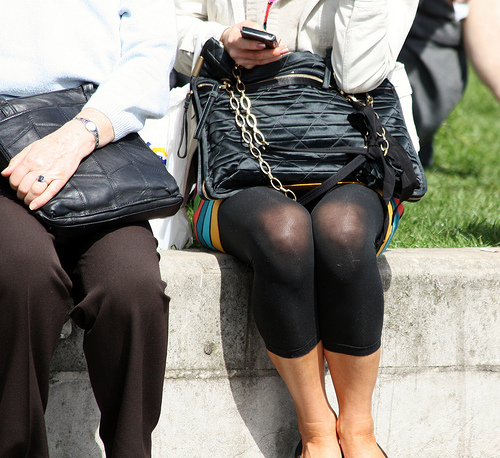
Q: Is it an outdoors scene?
A: Yes, it is outdoors.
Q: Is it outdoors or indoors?
A: It is outdoors.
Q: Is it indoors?
A: No, it is outdoors.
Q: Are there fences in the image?
A: No, there are no fences.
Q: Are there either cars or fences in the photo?
A: No, there are no fences or cars.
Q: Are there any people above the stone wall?
A: Yes, there are people above the wall.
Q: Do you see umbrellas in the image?
A: No, there are no umbrellas.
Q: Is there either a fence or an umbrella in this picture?
A: No, there are no umbrellas or fences.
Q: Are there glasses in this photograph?
A: No, there are no glasses.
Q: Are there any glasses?
A: No, there are no glasses.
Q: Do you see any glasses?
A: No, there are no glasses.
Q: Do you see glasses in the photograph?
A: No, there are no glasses.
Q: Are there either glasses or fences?
A: No, there are no glasses or fences.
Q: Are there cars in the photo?
A: No, there are no cars.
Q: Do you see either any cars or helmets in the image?
A: No, there are no cars or helmets.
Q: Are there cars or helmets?
A: No, there are no cars or helmets.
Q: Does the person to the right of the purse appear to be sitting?
A: Yes, the person is sitting.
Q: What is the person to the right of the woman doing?
A: The person is sitting.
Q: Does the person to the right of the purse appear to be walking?
A: No, the person is sitting.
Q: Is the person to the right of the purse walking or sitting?
A: The person is sitting.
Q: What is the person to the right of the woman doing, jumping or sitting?
A: The person is sitting.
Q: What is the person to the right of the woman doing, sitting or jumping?
A: The person is sitting.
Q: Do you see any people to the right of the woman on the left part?
A: Yes, there is a person to the right of the woman.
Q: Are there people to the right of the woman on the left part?
A: Yes, there is a person to the right of the woman.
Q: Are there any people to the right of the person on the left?
A: Yes, there is a person to the right of the woman.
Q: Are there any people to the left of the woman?
A: No, the person is to the right of the woman.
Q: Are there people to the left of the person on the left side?
A: No, the person is to the right of the woman.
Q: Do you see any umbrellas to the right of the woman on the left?
A: No, there is a person to the right of the woman.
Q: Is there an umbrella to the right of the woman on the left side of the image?
A: No, there is a person to the right of the woman.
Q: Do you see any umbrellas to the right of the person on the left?
A: No, there is a person to the right of the woman.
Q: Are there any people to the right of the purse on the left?
A: Yes, there is a person to the right of the purse.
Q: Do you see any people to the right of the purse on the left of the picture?
A: Yes, there is a person to the right of the purse.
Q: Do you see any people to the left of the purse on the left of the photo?
A: No, the person is to the right of the purse.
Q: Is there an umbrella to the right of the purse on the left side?
A: No, there is a person to the right of the purse.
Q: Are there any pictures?
A: No, there are no pictures.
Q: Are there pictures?
A: No, there are no pictures.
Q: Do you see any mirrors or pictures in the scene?
A: No, there are no pictures or mirrors.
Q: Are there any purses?
A: Yes, there is a purse.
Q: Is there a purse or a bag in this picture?
A: Yes, there is a purse.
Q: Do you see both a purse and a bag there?
A: Yes, there are both a purse and a bag.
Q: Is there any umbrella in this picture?
A: No, there are no umbrellas.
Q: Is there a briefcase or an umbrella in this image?
A: No, there are no umbrellas or briefcases.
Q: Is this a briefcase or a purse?
A: This is a purse.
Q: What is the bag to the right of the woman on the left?
A: The bag is a purse.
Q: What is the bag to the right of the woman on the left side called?
A: The bag is a purse.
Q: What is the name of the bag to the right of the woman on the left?
A: The bag is a purse.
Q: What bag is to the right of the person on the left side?
A: The bag is a purse.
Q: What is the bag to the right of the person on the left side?
A: The bag is a purse.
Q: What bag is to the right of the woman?
A: The bag is a purse.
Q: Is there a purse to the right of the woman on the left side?
A: Yes, there is a purse to the right of the woman.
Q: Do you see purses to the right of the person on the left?
A: Yes, there is a purse to the right of the woman.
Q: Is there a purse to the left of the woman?
A: No, the purse is to the right of the woman.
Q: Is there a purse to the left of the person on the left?
A: No, the purse is to the right of the woman.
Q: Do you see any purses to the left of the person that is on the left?
A: No, the purse is to the right of the woman.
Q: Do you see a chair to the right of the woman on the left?
A: No, there is a purse to the right of the woman.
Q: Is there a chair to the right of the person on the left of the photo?
A: No, there is a purse to the right of the woman.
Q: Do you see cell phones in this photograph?
A: Yes, there is a cell phone.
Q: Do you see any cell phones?
A: Yes, there is a cell phone.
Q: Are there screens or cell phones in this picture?
A: Yes, there is a cell phone.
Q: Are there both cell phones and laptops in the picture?
A: No, there is a cell phone but no laptops.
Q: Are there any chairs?
A: No, there are no chairs.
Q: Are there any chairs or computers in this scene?
A: No, there are no chairs or computers.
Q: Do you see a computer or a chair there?
A: No, there are no chairs or computers.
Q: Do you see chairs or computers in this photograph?
A: No, there are no chairs or computers.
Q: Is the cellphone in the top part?
A: Yes, the cellphone is in the top of the image.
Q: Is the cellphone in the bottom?
A: No, the cellphone is in the top of the image.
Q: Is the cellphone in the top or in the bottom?
A: The cellphone is in the top of the image.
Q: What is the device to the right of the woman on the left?
A: The device is a cell phone.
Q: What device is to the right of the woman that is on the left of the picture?
A: The device is a cell phone.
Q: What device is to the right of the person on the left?
A: The device is a cell phone.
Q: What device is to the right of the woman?
A: The device is a cell phone.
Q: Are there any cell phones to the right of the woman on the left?
A: Yes, there is a cell phone to the right of the woman.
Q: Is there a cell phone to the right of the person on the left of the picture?
A: Yes, there is a cell phone to the right of the woman.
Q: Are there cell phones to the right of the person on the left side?
A: Yes, there is a cell phone to the right of the woman.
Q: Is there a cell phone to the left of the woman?
A: No, the cell phone is to the right of the woman.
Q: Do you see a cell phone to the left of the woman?
A: No, the cell phone is to the right of the woman.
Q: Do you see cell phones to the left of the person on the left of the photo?
A: No, the cell phone is to the right of the woman.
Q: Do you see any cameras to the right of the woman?
A: No, there is a cell phone to the right of the woman.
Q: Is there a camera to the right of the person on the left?
A: No, there is a cell phone to the right of the woman.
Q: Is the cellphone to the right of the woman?
A: Yes, the cellphone is to the right of the woman.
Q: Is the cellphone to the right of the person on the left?
A: Yes, the cellphone is to the right of the woman.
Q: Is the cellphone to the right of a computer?
A: No, the cellphone is to the right of the woman.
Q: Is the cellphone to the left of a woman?
A: No, the cellphone is to the right of a woman.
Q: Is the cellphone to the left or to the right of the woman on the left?
A: The cellphone is to the right of the woman.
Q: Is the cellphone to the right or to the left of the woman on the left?
A: The cellphone is to the right of the woman.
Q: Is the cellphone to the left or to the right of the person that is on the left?
A: The cellphone is to the right of the woman.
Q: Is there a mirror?
A: No, there are no mirrors.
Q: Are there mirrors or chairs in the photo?
A: No, there are no mirrors or chairs.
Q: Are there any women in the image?
A: Yes, there is a woman.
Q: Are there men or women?
A: Yes, there is a woman.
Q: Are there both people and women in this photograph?
A: Yes, there are both a woman and a person.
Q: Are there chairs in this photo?
A: No, there are no chairs.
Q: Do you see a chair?
A: No, there are no chairs.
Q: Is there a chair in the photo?
A: No, there are no chairs.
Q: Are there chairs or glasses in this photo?
A: No, there are no chairs or glasses.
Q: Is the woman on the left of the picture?
A: Yes, the woman is on the left of the image.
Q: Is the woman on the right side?
A: No, the woman is on the left of the image.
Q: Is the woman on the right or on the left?
A: The woman is on the left of the image.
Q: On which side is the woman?
A: The woman is on the left of the image.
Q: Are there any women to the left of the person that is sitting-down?
A: Yes, there is a woman to the left of the person.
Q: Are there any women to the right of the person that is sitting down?
A: No, the woman is to the left of the person.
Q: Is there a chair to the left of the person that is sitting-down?
A: No, there is a woman to the left of the person.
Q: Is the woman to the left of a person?
A: Yes, the woman is to the left of a person.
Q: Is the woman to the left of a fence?
A: No, the woman is to the left of a person.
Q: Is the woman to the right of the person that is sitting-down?
A: No, the woman is to the left of the person.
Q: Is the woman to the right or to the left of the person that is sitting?
A: The woman is to the left of the person.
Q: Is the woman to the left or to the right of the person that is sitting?
A: The woman is to the left of the person.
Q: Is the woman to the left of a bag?
A: Yes, the woman is to the left of a bag.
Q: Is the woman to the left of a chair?
A: No, the woman is to the left of a bag.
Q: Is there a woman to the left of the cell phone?
A: Yes, there is a woman to the left of the cell phone.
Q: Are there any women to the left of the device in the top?
A: Yes, there is a woman to the left of the cell phone.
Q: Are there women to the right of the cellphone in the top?
A: No, the woman is to the left of the cell phone.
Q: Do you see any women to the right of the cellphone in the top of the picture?
A: No, the woman is to the left of the cell phone.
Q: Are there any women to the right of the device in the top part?
A: No, the woman is to the left of the cell phone.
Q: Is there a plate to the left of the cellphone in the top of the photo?
A: No, there is a woman to the left of the cell phone.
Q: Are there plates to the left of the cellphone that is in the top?
A: No, there is a woman to the left of the cell phone.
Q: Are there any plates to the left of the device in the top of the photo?
A: No, there is a woman to the left of the cell phone.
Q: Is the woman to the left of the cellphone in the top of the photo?
A: Yes, the woman is to the left of the cell phone.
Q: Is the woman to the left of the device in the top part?
A: Yes, the woman is to the left of the cell phone.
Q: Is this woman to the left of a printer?
A: No, the woman is to the left of the cell phone.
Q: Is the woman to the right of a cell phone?
A: No, the woman is to the left of a cell phone.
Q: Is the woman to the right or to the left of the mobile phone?
A: The woman is to the left of the mobile phone.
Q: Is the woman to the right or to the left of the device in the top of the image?
A: The woman is to the left of the mobile phone.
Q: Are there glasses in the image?
A: No, there are no glasses.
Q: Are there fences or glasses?
A: No, there are no glasses or fences.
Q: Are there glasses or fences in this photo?
A: No, there are no glasses or fences.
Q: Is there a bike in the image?
A: No, there are no bikes.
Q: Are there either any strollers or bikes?
A: No, there are no bikes or strollers.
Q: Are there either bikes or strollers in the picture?
A: No, there are no bikes or strollers.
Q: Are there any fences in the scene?
A: No, there are no fences.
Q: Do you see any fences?
A: No, there are no fences.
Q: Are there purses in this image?
A: Yes, there is a purse.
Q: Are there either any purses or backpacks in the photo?
A: Yes, there is a purse.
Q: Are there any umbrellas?
A: No, there are no umbrellas.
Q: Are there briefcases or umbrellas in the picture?
A: No, there are no umbrellas or briefcases.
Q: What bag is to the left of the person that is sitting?
A: The bag is a purse.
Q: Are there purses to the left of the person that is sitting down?
A: Yes, there is a purse to the left of the person.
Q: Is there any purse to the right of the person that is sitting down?
A: No, the purse is to the left of the person.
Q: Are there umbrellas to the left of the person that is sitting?
A: No, there is a purse to the left of the person.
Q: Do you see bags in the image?
A: Yes, there is a bag.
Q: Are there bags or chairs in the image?
A: Yes, there is a bag.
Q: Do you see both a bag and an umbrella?
A: No, there is a bag but no umbrellas.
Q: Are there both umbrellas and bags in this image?
A: No, there is a bag but no umbrellas.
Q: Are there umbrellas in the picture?
A: No, there are no umbrellas.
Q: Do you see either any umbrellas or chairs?
A: No, there are no umbrellas or chairs.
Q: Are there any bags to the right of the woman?
A: Yes, there is a bag to the right of the woman.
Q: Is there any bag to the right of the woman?
A: Yes, there is a bag to the right of the woman.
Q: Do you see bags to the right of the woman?
A: Yes, there is a bag to the right of the woman.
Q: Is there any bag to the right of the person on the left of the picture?
A: Yes, there is a bag to the right of the woman.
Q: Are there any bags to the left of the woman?
A: No, the bag is to the right of the woman.